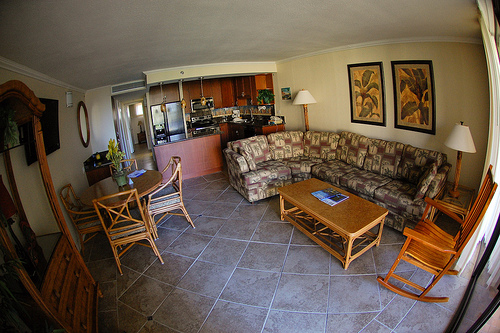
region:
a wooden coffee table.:
[271, 168, 392, 277]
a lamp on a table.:
[433, 122, 483, 204]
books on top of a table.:
[305, 180, 352, 219]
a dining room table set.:
[40, 141, 202, 284]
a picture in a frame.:
[326, 57, 387, 138]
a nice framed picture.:
[388, 55, 446, 140]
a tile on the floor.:
[216, 251, 286, 316]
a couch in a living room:
[221, 130, 453, 234]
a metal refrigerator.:
[146, 98, 191, 156]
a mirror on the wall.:
[64, 83, 104, 163]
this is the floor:
[181, 236, 271, 301]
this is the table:
[287, 182, 351, 239]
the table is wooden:
[329, 202, 366, 228]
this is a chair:
[421, 205, 468, 290]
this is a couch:
[344, 138, 400, 190]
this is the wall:
[441, 59, 466, 99]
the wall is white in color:
[301, 59, 325, 86]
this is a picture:
[390, 57, 435, 123]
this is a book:
[319, 186, 344, 200]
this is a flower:
[106, 140, 132, 189]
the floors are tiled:
[187, 230, 303, 317]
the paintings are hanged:
[339, 57, 443, 126]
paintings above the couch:
[340, 57, 434, 171]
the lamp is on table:
[441, 117, 476, 211]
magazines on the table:
[277, 175, 372, 276]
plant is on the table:
[99, 137, 140, 192]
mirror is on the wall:
[71, 100, 99, 146]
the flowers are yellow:
[102, 140, 132, 163]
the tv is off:
[23, 97, 66, 158]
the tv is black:
[20, 90, 80, 165]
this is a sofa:
[249, 130, 359, 175]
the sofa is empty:
[273, 133, 360, 166]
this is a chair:
[405, 206, 464, 281]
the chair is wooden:
[399, 207, 466, 288]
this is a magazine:
[312, 188, 344, 205]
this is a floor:
[202, 230, 277, 331]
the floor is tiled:
[204, 230, 285, 331]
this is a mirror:
[75, 101, 89, 145]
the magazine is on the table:
[312, 184, 350, 204]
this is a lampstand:
[438, 122, 483, 191]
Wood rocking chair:
[373, 161, 498, 313]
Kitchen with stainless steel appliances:
[143, 67, 283, 184]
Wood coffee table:
[269, 174, 390, 273]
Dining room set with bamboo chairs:
[53, 152, 212, 282]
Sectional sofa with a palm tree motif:
[219, 123, 454, 238]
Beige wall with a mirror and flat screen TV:
[11, 76, 95, 246]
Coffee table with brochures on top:
[269, 172, 392, 276]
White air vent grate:
[103, 75, 148, 100]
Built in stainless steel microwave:
[186, 93, 220, 115]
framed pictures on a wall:
[361, 55, 441, 135]